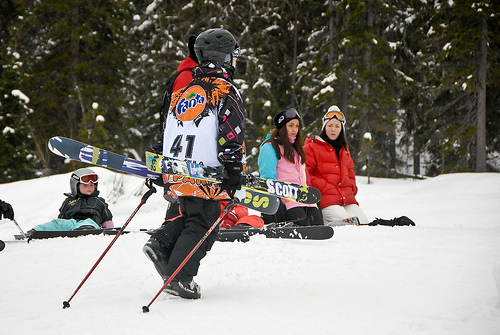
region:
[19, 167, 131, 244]
Child with gray helmet and goggles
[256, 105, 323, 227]
Girl with blue and pink jacket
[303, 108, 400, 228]
Girl with red jacket and white snow pants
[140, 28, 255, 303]
Person wearing a jacket with Fanta on the back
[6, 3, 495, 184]
Pine trees covered with snow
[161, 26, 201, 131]
Person in red jacket with white hat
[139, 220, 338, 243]
Black ski in snow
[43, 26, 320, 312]
Person carrying to skis and poles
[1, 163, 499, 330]
Ground covered with white snow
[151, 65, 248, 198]
Black, white and orange jacket with number 41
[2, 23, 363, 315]
young children in ski outfits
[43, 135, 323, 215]
skis being carried along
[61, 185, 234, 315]
red and black ski poles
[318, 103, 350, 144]
girl wearing hat and goggles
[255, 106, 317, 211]
girl wearing pink and teal ski jacket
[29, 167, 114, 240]
little boy layin back on the snow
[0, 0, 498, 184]
woods behind the ski area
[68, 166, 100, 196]
little boy with hat and goggles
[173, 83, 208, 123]
Fanta logo on boys back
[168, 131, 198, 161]
balck number on the ski jacket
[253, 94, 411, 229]
two girls sitting down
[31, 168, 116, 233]
a kid sitting down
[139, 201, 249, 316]
a pink ski pole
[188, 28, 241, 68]
a black ski helmet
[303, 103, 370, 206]
a woman wearing a red jacket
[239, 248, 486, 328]
a thick layer of snow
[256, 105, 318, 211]
a woman wearing a pink and blue jacket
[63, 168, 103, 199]
a kid wearing a ski helmet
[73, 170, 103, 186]
a pair of ski goggles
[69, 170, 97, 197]
a kid wearing ski goggles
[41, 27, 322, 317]
child holding pole and ski in each hand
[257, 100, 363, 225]
girls kneeling in snow next to each other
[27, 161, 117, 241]
child leaning back in snow with head turned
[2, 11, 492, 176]
trees in back of people with snow on branches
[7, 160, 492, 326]
snow covering ground with low drifts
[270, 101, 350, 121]
goggles placed over face on head coverings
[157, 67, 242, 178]
black sleeves covered in colorful squares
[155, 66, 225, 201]
white jacket with number and company logos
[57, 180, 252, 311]
red poles slanted behind black pants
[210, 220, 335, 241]
gray skis on edge on snow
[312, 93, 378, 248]
This is a person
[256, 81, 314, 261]
This is a person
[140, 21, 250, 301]
This is a person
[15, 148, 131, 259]
This is a person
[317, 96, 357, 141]
Head of a person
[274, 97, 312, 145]
Head of a person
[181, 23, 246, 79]
Head of a person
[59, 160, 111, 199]
Head of a person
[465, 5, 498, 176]
This is a tree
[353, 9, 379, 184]
This is a tree